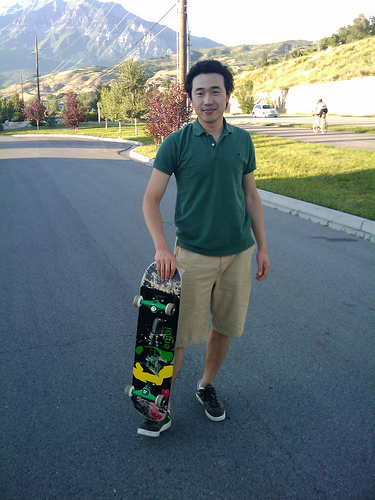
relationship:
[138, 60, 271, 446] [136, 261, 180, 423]
man holding skateboard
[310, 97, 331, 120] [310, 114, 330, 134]
person on a bicycle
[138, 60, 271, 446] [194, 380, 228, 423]
man wearing a shoe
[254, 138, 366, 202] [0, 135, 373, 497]
grass by road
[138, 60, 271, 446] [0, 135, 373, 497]
man on road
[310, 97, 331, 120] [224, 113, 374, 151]
person on a road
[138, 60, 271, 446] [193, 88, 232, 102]
man has eyes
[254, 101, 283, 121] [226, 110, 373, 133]
car on road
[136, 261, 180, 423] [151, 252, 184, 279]
skateboard in right hand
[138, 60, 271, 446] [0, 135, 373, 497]
man in road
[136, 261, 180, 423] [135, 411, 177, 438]
skateboard on foot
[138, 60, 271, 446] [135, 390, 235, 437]
man wearing shoes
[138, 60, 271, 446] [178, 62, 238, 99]
man has hair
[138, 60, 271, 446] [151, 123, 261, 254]
man wearing a shirt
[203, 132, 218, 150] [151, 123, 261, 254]
buttons are on shirt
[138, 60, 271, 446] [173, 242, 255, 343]
man wearing shorts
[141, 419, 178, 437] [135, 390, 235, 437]
trim on shoes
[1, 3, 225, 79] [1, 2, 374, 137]
mountain in background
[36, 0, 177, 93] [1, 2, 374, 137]
telephone lines in background